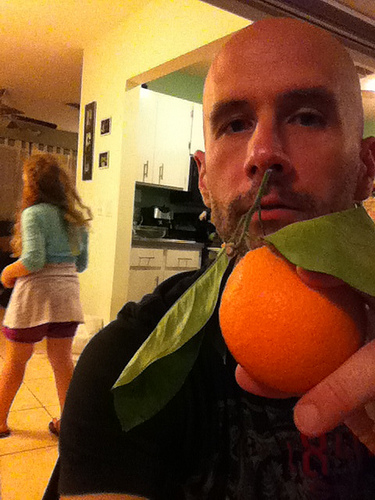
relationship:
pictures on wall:
[78, 93, 120, 189] [76, 6, 263, 351]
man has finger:
[39, 10, 374, 499] [291, 338, 375, 440]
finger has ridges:
[291, 338, 375, 440] [323, 376, 358, 408]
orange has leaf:
[219, 239, 372, 385] [103, 157, 277, 439]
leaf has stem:
[103, 157, 277, 439] [228, 161, 279, 252]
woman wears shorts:
[1, 145, 92, 459] [2, 313, 83, 347]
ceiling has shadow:
[1, 0, 186, 105] [4, 41, 82, 102]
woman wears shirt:
[1, 145, 92, 459] [2, 254, 93, 332]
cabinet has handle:
[139, 87, 186, 189] [155, 160, 168, 184]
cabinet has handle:
[139, 87, 186, 189] [140, 159, 151, 182]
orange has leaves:
[219, 239, 372, 385] [103, 160, 373, 445]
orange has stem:
[219, 239, 372, 385] [228, 161, 279, 252]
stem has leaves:
[228, 161, 279, 252] [103, 160, 373, 445]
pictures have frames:
[78, 93, 120, 189] [85, 102, 109, 179]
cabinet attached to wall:
[139, 87, 186, 189] [144, 68, 374, 143]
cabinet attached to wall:
[188, 101, 207, 160] [144, 68, 374, 143]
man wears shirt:
[39, 10, 374, 499] [53, 253, 372, 500]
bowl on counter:
[133, 222, 172, 238] [127, 241, 205, 311]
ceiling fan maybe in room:
[0, 83, 35, 135] [0, 0, 159, 329]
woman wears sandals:
[1, 145, 92, 459] [1, 416, 64, 443]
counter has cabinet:
[127, 241, 205, 311] [127, 247, 200, 314]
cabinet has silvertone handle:
[127, 247, 200, 314] [152, 274, 162, 290]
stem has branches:
[228, 161, 279, 252] [225, 203, 271, 255]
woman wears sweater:
[1, 145, 92, 459] [13, 203, 93, 272]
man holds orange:
[39, 10, 374, 499] [219, 239, 372, 385]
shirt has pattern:
[53, 253, 372, 500] [197, 343, 373, 500]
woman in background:
[1, 145, 92, 459] [0, 0, 257, 500]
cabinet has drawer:
[127, 247, 200, 314] [130, 247, 164, 267]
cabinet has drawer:
[127, 247, 200, 314] [166, 250, 198, 270]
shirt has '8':
[53, 253, 372, 500] [298, 426, 334, 482]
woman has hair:
[1, 145, 92, 459] [7, 146, 98, 261]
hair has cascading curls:
[7, 146, 98, 261] [4, 182, 97, 266]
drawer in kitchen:
[130, 247, 164, 267] [130, 60, 372, 310]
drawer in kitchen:
[166, 250, 198, 270] [130, 60, 372, 310]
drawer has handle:
[130, 247, 164, 267] [134, 254, 160, 265]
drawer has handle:
[166, 250, 198, 270] [173, 256, 194, 265]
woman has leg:
[1, 145, 92, 459] [2, 335, 39, 439]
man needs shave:
[39, 10, 374, 499] [200, 175, 361, 252]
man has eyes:
[39, 10, 374, 499] [213, 104, 333, 146]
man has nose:
[39, 10, 374, 499] [241, 99, 299, 181]